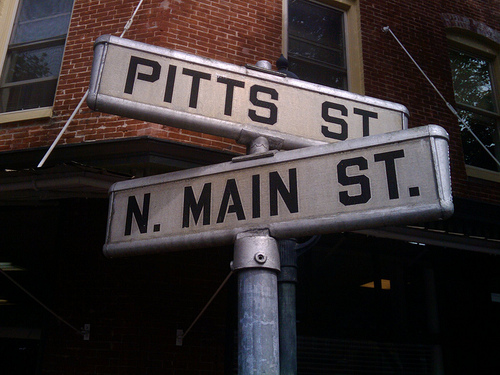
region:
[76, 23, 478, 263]
street signs on a pole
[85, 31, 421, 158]
top of street sign says PITTS ST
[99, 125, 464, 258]
low street sign says N. MAIN ST.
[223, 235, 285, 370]
pole of street sign is gray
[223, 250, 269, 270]
two bolts on a pole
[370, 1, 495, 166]
a wire a gray wire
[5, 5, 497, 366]
building behind signs is made of bricks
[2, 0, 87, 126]
a window on side wall of building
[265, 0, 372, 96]
a window has a yellow frame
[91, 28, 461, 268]
black letters on signs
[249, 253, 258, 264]
THE SCREW IS VISIBLE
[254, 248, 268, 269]
THE SCREW IS VISIBLE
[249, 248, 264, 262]
THE SCREW IS VISIBLE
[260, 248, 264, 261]
THE SCREW IS VISIBLE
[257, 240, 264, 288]
THE SCREW IS VISIBLE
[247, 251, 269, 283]
THE SCREW IS VISIBLE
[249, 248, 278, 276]
THE SCREW IS VISIBLE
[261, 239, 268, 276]
THE SCREW IS VISIBLE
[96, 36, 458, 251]
these are two street signs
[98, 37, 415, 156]
the signs are rectangular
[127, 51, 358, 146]
there are writings on the board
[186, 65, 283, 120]
the writings are in bold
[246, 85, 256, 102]
the writings are black in color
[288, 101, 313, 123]
the street sign is white in color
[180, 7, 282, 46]
this is a building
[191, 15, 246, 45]
the wall is made of bricks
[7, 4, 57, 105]
this is a window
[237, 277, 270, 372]
this is a metallic pole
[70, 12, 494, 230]
two white street signs on metal pole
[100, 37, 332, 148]
white street sign says Pitts St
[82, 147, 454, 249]
white street sign says n. main st.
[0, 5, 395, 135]
two windows visible in photograph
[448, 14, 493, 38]
white writing over window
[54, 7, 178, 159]
white support pole on building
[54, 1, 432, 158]
brick building in photograph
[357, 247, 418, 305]
light on somewhere in building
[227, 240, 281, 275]
small hole on metal street sign pole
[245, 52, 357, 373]
second metal pole behind street signs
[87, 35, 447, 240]
two street signs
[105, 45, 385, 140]
sign that says PITTS ST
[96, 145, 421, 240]
sign that says N. MAIN ST.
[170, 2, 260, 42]
bricks on building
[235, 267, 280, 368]
silver pole sign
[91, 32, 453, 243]
white street signs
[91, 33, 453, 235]
street signs with black lettering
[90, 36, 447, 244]
black lettering on street signs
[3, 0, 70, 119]
window in the building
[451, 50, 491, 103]
reflection in the window